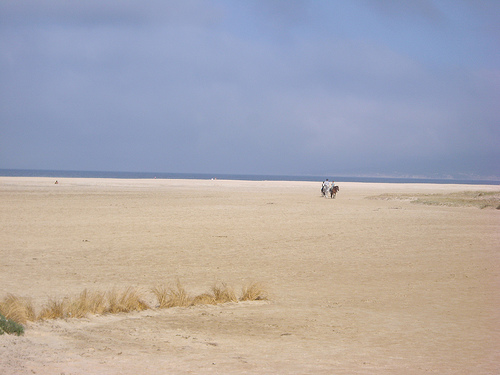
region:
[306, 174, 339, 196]
two people walking on large beach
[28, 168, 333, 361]
large sandy area before water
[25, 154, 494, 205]
ocean in the background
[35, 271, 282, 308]
brown grass growing in sand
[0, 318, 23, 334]
green leaves on top of sand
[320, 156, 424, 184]
white clouds in the distance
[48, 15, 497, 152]
clear blue sky above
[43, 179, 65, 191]
small object on the sand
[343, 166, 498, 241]
hill on the right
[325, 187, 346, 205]
person sitting on horse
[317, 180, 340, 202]
horses on the beack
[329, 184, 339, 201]
this horse is brown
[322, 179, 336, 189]
people riding the horses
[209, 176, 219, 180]
two dots on the beach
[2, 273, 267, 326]
brown grass on the beach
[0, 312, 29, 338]
a tuft of green grass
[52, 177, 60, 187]
a speck on the beach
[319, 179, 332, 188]
the person is wearing white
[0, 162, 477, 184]
water beyond the beach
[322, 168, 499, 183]
the mountains are distant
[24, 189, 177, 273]
big sandy tan beach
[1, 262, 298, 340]
plants growing on the beach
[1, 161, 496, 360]
extremely large beach with a lot of sand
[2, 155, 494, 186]
water far off in the distance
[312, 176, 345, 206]
people walking to the waters edge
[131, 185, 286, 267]
millions of tan grains of sand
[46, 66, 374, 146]
perfect blue skies no clouds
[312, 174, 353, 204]
a family going to the beach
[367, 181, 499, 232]
larger pile of sand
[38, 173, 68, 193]
person laying on the beach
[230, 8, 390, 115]
this is the sky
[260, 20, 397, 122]
the sky is clear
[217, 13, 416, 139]
the sky is blue in color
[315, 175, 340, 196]
these are people riding horse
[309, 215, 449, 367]
this is the ground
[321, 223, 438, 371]
the ground is dry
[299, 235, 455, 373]
the ground is brown in color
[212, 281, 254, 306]
these are the grass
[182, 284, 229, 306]
the grass are dry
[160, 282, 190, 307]
the grass are short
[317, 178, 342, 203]
Beachgoers on the beach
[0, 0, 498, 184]
Foggy, unclear sky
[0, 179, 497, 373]
Sandy beach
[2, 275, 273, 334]
Yellow grass growing in sand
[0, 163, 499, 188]
Ocean and shore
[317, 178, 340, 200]
Couple of people on the beach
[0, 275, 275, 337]
Grass growing on beach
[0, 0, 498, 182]
Unclear, daytime sky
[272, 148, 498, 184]
Land off in distance separated by water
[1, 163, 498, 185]
Sandy beach shoreline